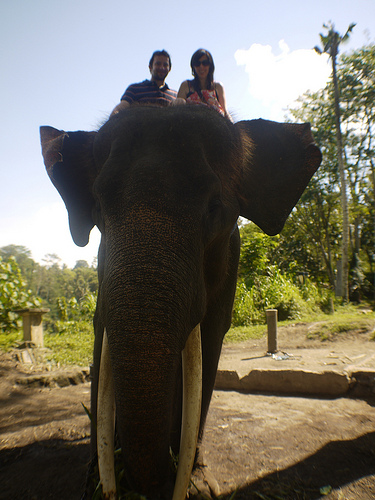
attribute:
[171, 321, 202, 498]
tusk — white, ivory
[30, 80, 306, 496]
elephant — large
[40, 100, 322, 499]
elephant — brown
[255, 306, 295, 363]
pole — metal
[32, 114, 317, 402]
elephant — large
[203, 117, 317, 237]
elephant — large